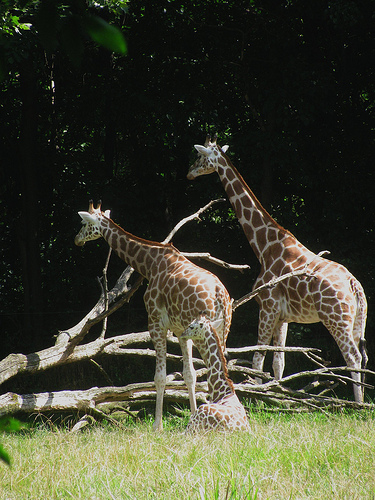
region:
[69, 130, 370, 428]
Two giraffes standing by some wood.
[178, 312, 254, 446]
A giraffe sitting in tall grass.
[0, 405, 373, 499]
A field of tall grass.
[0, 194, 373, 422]
Bare wood logs near the giraffes.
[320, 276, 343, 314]
A patch of brown spotted fur.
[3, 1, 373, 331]
Dark brown and green trees behind the giraffes.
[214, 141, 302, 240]
A brown mane on a giraffe.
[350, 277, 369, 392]
A long giraffe tail.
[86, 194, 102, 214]
A pair of brown and black giraffe horns.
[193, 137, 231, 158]
Ears on a giraffe.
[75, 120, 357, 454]
three giraffes in field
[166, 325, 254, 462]
giraffe is lying on grass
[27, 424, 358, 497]
grass is green and light brown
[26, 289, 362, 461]
downed tree near giraffes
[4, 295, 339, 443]
tree has bare branches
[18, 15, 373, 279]
thick green leaves on trees behind giraffes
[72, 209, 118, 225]
giraffe has white ears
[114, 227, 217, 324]
brown and white spots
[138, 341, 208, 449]
giraffe has white legs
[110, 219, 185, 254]
giraffe has thin brown mane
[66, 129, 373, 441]
three giraffes in grass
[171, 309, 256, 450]
baby giraffe sitting in the grass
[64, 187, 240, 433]
juvenile giraffe standing before fallen logs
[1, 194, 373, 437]
fallen tree branches on the ground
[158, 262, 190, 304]
brown and white spots on giraffe fur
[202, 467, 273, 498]
blades of green grass in field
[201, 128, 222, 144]
two ossicones on top of giraffe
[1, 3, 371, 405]
tall trees and foliage before fallen tree branches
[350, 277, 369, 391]
long giraffe tail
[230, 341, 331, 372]
brown treet branch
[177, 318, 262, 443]
a small giraffe sitting on the ground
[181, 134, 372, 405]
a large giraffe standing up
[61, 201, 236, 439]
a large giraffe with its head lowered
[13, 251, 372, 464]
a dead fallen tree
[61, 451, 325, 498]
field of grass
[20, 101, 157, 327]
thick forrest of trees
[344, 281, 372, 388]
tail of giraffe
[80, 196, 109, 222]
horns on a girrafe's head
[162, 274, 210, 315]
brown spots on a giraffe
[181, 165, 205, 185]
mouth of a large giraffe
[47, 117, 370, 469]
three giraffes in the grass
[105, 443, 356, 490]
tall green grass by the giraffe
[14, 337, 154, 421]
trunks of trees on ground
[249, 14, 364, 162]
green leaves on trees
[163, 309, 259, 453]
giraffe laying in the grass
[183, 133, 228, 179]
head of a giraffe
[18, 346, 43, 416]
shadow on a tree trunk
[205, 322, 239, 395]
mane of a giraffe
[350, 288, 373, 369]
tail of a giraffe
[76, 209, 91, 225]
left ear of a giraffe